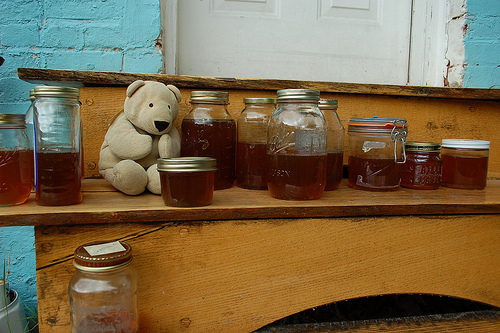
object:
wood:
[1, 67, 500, 332]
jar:
[0, 111, 36, 209]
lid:
[0, 113, 28, 129]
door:
[161, 0, 432, 87]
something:
[1, 149, 36, 208]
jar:
[31, 84, 84, 208]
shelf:
[0, 178, 500, 228]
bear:
[97, 79, 182, 197]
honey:
[35, 150, 83, 207]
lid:
[440, 138, 491, 150]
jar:
[264, 88, 330, 200]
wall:
[1, 1, 498, 331]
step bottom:
[33, 213, 498, 332]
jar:
[345, 115, 409, 193]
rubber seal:
[346, 122, 409, 129]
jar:
[156, 155, 218, 208]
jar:
[179, 90, 237, 192]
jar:
[235, 97, 279, 190]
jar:
[401, 141, 443, 192]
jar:
[440, 137, 491, 190]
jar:
[317, 98, 345, 192]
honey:
[179, 117, 237, 191]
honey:
[235, 140, 268, 190]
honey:
[264, 151, 328, 202]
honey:
[324, 152, 344, 192]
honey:
[441, 153, 491, 191]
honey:
[347, 153, 403, 193]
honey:
[159, 170, 217, 207]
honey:
[401, 150, 445, 191]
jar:
[67, 238, 139, 332]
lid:
[72, 238, 135, 273]